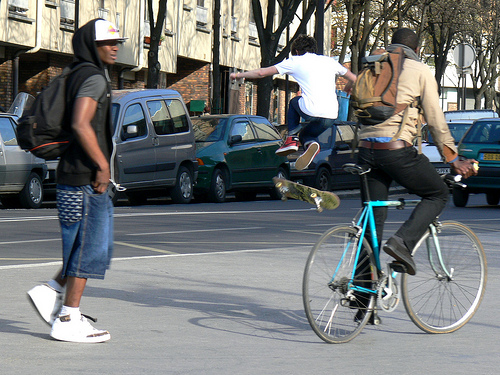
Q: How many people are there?
A: Three.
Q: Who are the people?
A: Three guys.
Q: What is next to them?
A: Cars.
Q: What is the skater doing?
A: A skate move.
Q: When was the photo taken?
A: During day.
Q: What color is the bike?
A: Blue.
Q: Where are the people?
A: In the street.